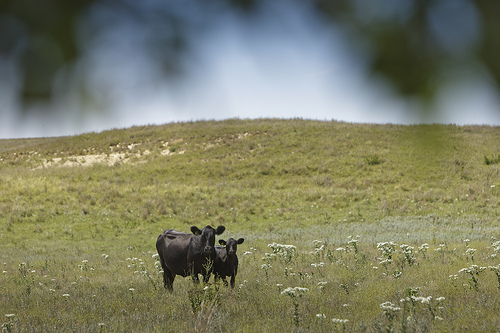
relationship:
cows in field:
[155, 224, 225, 293] [4, 115, 499, 333]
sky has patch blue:
[0, 1, 498, 121] [199, 21, 316, 71]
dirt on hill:
[49, 150, 150, 170] [4, 115, 499, 333]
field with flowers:
[4, 115, 499, 333] [377, 287, 447, 333]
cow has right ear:
[214, 233, 245, 291] [234, 235, 248, 247]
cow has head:
[214, 233, 245, 291] [218, 235, 247, 259]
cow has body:
[214, 233, 245, 291] [215, 256, 241, 282]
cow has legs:
[214, 233, 245, 291] [210, 273, 240, 291]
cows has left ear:
[155, 224, 225, 293] [188, 222, 205, 239]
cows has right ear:
[155, 224, 225, 293] [214, 222, 227, 237]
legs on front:
[192, 267, 212, 291] [187, 220, 224, 289]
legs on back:
[161, 269, 177, 294] [154, 223, 184, 296]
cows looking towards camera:
[152, 219, 246, 294] [3, 3, 497, 333]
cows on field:
[155, 224, 225, 293] [4, 115, 499, 333]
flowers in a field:
[377, 287, 447, 333] [4, 115, 499, 333]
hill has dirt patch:
[4, 115, 499, 333] [49, 150, 150, 170]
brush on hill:
[365, 153, 387, 169] [4, 115, 499, 333]